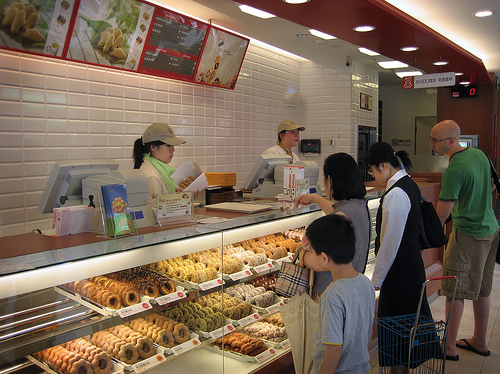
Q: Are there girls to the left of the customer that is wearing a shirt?
A: Yes, there is a girl to the left of the customer.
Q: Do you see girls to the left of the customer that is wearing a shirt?
A: Yes, there is a girl to the left of the customer.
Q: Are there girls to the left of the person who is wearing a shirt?
A: Yes, there is a girl to the left of the customer.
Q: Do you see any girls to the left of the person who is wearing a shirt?
A: Yes, there is a girl to the left of the customer.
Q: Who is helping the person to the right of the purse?
A: The girl is helping the customer.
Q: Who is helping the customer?
A: The girl is helping the customer.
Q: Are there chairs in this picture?
A: No, there are no chairs.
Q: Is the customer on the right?
A: Yes, the customer is on the right of the image.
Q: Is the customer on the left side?
A: No, the customer is on the right of the image.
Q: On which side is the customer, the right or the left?
A: The customer is on the right of the image.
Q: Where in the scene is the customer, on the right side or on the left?
A: The customer is on the right of the image.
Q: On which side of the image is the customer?
A: The customer is on the right of the image.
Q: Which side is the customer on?
A: The customer is on the right of the image.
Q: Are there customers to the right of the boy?
A: Yes, there is a customer to the right of the boy.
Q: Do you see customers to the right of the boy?
A: Yes, there is a customer to the right of the boy.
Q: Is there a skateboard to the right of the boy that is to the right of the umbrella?
A: No, there is a customer to the right of the boy.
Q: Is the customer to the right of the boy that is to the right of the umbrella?
A: Yes, the customer is to the right of the boy.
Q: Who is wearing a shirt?
A: The customer is wearing a shirt.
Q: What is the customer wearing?
A: The customer is wearing a shirt.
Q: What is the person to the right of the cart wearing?
A: The customer is wearing a shirt.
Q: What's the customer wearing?
A: The customer is wearing a shirt.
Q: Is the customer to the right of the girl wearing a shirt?
A: Yes, the customer is wearing a shirt.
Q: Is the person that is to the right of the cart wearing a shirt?
A: Yes, the customer is wearing a shirt.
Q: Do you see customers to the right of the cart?
A: Yes, there is a customer to the right of the cart.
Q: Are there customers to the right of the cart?
A: Yes, there is a customer to the right of the cart.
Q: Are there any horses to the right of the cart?
A: No, there is a customer to the right of the cart.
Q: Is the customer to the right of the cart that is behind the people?
A: Yes, the customer is to the right of the cart.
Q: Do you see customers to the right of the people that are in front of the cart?
A: Yes, there is a customer to the right of the people.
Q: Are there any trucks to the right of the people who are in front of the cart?
A: No, there is a customer to the right of the people.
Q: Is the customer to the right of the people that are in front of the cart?
A: Yes, the customer is to the right of the people.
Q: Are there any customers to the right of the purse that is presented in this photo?
A: Yes, there is a customer to the right of the purse.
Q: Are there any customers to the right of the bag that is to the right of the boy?
A: Yes, there is a customer to the right of the purse.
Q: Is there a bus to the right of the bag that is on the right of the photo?
A: No, there is a customer to the right of the purse.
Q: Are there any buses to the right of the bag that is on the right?
A: No, there is a customer to the right of the purse.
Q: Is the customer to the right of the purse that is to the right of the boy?
A: Yes, the customer is to the right of the purse.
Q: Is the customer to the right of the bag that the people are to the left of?
A: Yes, the customer is to the right of the purse.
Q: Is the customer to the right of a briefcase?
A: No, the customer is to the right of the purse.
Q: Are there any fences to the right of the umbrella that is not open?
A: No, there is a customer to the right of the umbrella.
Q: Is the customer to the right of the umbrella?
A: Yes, the customer is to the right of the umbrella.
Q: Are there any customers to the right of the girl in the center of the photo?
A: Yes, there is a customer to the right of the girl.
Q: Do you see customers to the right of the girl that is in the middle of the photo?
A: Yes, there is a customer to the right of the girl.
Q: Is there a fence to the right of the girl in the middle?
A: No, there is a customer to the right of the girl.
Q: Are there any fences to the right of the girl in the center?
A: No, there is a customer to the right of the girl.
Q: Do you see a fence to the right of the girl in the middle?
A: No, there is a customer to the right of the girl.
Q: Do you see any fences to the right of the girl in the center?
A: No, there is a customer to the right of the girl.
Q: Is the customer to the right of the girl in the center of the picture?
A: Yes, the customer is to the right of the girl.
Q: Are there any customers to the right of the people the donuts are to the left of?
A: Yes, there is a customer to the right of the people.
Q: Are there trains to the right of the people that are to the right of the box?
A: No, there is a customer to the right of the people.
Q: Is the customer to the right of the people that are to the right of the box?
A: Yes, the customer is to the right of the people.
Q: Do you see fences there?
A: No, there are no fences.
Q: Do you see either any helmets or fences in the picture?
A: No, there are no fences or helmets.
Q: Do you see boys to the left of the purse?
A: Yes, there is a boy to the left of the purse.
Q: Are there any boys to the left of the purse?
A: Yes, there is a boy to the left of the purse.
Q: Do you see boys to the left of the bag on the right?
A: Yes, there is a boy to the left of the purse.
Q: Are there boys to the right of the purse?
A: No, the boy is to the left of the purse.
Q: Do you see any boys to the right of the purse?
A: No, the boy is to the left of the purse.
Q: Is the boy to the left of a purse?
A: Yes, the boy is to the left of a purse.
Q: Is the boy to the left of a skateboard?
A: No, the boy is to the left of a purse.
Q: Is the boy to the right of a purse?
A: No, the boy is to the left of a purse.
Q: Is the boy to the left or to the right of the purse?
A: The boy is to the left of the purse.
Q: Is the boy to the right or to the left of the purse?
A: The boy is to the left of the purse.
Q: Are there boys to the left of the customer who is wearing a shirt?
A: Yes, there is a boy to the left of the customer.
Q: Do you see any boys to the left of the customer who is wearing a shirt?
A: Yes, there is a boy to the left of the customer.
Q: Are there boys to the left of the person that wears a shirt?
A: Yes, there is a boy to the left of the customer.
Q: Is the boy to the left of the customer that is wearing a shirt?
A: Yes, the boy is to the left of the customer.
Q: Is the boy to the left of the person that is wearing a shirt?
A: Yes, the boy is to the left of the customer.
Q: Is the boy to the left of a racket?
A: No, the boy is to the left of the customer.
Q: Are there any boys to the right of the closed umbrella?
A: Yes, there is a boy to the right of the umbrella.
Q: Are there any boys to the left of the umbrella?
A: No, the boy is to the right of the umbrella.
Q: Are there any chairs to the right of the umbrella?
A: No, there is a boy to the right of the umbrella.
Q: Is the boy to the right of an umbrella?
A: Yes, the boy is to the right of an umbrella.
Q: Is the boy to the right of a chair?
A: No, the boy is to the right of an umbrella.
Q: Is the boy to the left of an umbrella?
A: No, the boy is to the right of an umbrella.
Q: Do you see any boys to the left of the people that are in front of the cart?
A: Yes, there is a boy to the left of the people.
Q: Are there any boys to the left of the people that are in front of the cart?
A: Yes, there is a boy to the left of the people.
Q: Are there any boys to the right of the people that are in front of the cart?
A: No, the boy is to the left of the people.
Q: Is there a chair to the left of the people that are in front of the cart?
A: No, there is a boy to the left of the people.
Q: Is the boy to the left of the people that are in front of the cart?
A: Yes, the boy is to the left of the people.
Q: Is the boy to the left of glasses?
A: No, the boy is to the left of the people.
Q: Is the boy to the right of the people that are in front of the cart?
A: No, the boy is to the left of the people.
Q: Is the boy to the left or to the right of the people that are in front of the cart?
A: The boy is to the left of the people.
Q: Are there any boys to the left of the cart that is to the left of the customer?
A: Yes, there is a boy to the left of the cart.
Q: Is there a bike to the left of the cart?
A: No, there is a boy to the left of the cart.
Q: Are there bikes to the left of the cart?
A: No, there is a boy to the left of the cart.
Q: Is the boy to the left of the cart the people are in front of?
A: Yes, the boy is to the left of the cart.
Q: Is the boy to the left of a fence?
A: No, the boy is to the left of the cart.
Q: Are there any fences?
A: No, there are no fences.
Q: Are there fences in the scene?
A: No, there are no fences.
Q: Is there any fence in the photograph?
A: No, there are no fences.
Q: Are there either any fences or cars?
A: No, there are no fences or cars.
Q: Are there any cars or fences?
A: No, there are no fences or cars.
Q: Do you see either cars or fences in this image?
A: No, there are no fences or cars.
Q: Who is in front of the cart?
A: The people are in front of the cart.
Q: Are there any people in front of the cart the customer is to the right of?
A: Yes, there are people in front of the cart.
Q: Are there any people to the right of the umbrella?
A: Yes, there are people to the right of the umbrella.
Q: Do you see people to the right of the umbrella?
A: Yes, there are people to the right of the umbrella.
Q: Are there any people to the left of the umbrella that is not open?
A: No, the people are to the right of the umbrella.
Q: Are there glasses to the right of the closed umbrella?
A: No, there are people to the right of the umbrella.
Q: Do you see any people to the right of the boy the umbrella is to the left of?
A: Yes, there are people to the right of the boy.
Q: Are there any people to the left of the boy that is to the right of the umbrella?
A: No, the people are to the right of the boy.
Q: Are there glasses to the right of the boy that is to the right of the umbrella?
A: No, there are people to the right of the boy.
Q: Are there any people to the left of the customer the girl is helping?
A: Yes, there are people to the left of the customer.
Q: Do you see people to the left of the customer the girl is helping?
A: Yes, there are people to the left of the customer.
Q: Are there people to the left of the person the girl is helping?
A: Yes, there are people to the left of the customer.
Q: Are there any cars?
A: No, there are no cars.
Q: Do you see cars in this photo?
A: No, there are no cars.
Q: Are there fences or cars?
A: No, there are no cars or fences.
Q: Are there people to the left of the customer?
A: Yes, there are people to the left of the customer.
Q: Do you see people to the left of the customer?
A: Yes, there are people to the left of the customer.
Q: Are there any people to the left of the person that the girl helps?
A: Yes, there are people to the left of the customer.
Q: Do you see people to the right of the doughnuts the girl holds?
A: Yes, there are people to the right of the donuts.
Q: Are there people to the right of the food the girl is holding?
A: Yes, there are people to the right of the donuts.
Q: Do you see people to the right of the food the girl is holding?
A: Yes, there are people to the right of the donuts.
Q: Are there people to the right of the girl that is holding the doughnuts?
A: Yes, there are people to the right of the girl.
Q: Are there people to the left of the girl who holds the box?
A: No, the people are to the right of the girl.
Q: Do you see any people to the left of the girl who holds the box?
A: No, the people are to the right of the girl.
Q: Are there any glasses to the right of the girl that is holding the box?
A: No, there are people to the right of the girl.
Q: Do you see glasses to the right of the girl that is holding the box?
A: No, there are people to the right of the girl.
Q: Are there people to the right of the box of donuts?
A: Yes, there are people to the right of the box.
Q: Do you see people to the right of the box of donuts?
A: Yes, there are people to the right of the box.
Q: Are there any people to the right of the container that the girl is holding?
A: Yes, there are people to the right of the box.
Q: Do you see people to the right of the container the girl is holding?
A: Yes, there are people to the right of the box.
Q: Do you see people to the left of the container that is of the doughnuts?
A: No, the people are to the right of the box.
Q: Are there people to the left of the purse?
A: Yes, there are people to the left of the purse.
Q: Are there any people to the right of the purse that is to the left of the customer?
A: No, the people are to the left of the purse.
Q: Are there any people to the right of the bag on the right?
A: No, the people are to the left of the purse.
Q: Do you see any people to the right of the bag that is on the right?
A: No, the people are to the left of the purse.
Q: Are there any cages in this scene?
A: No, there are no cages.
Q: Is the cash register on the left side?
A: Yes, the cash register is on the left of the image.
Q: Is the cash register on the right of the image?
A: No, the cash register is on the left of the image.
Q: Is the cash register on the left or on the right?
A: The cash register is on the left of the image.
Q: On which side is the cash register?
A: The cash register is on the left of the image.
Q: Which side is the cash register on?
A: The cash register is on the left of the image.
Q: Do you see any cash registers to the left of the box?
A: Yes, there is a cash register to the left of the box.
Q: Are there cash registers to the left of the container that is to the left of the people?
A: Yes, there is a cash register to the left of the box.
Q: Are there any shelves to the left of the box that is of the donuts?
A: No, there is a cash register to the left of the box.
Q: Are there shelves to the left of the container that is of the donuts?
A: No, there is a cash register to the left of the box.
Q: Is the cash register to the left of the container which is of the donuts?
A: Yes, the cash register is to the left of the box.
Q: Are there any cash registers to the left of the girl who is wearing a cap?
A: Yes, there is a cash register to the left of the girl.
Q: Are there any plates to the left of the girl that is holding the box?
A: No, there is a cash register to the left of the girl.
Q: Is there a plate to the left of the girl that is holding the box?
A: No, there is a cash register to the left of the girl.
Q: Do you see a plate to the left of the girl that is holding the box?
A: No, there is a cash register to the left of the girl.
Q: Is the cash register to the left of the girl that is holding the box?
A: Yes, the cash register is to the left of the girl.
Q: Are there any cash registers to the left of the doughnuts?
A: Yes, there is a cash register to the left of the doughnuts.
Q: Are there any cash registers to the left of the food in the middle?
A: Yes, there is a cash register to the left of the doughnuts.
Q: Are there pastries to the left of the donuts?
A: No, there is a cash register to the left of the donuts.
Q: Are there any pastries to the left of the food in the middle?
A: No, there is a cash register to the left of the donuts.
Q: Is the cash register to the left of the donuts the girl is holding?
A: Yes, the cash register is to the left of the donuts.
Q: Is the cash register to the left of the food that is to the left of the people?
A: Yes, the cash register is to the left of the donuts.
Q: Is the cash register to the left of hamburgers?
A: No, the cash register is to the left of the donuts.